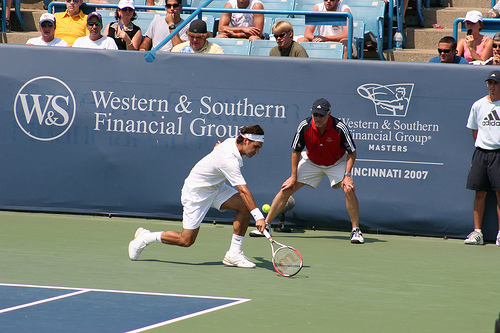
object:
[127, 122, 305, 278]
tennis player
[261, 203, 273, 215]
tennis ball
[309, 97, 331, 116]
cap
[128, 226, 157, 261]
tennis show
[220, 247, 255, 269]
tennis show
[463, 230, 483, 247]
tennis show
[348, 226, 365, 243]
tennis show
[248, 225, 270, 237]
tennis show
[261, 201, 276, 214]
ball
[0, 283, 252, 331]
tennis court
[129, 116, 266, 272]
man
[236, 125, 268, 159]
head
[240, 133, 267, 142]
headband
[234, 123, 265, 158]
sweatband head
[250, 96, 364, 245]
man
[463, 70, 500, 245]
man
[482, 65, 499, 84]
hat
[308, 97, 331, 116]
hat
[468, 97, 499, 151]
addidas t-shirt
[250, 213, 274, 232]
hand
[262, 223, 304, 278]
racket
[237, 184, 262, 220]
arm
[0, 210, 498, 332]
court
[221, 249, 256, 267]
shoe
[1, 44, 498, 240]
banner advertisement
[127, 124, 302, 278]
male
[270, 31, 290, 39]
sunglasses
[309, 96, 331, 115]
baseball hat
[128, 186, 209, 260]
leg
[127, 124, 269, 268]
man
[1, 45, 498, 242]
banner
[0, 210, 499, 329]
tennis court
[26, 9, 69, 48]
man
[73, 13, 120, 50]
man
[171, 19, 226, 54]
man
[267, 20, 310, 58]
man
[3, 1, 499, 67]
stands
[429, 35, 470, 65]
man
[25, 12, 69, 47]
man seated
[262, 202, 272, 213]
tennis ball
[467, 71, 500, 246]
ball-boy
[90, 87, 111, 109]
letter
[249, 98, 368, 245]
man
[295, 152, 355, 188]
shorts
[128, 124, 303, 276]
player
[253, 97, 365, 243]
linesman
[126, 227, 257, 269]
tennis shoe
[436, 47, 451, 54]
sunglasses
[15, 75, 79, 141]
logo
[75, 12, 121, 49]
spectator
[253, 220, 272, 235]
hand